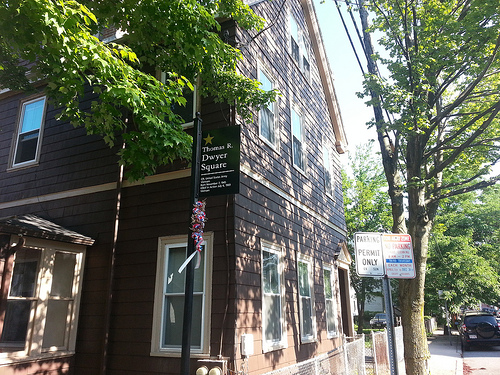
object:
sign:
[198, 123, 243, 196]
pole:
[180, 106, 203, 374]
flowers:
[188, 197, 214, 257]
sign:
[354, 229, 390, 278]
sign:
[381, 227, 417, 283]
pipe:
[93, 4, 136, 375]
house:
[3, 2, 352, 369]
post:
[382, 278, 400, 374]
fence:
[246, 326, 408, 374]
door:
[339, 268, 351, 342]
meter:
[193, 358, 229, 374]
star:
[202, 132, 218, 146]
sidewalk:
[434, 327, 463, 374]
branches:
[456, 6, 498, 72]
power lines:
[336, 1, 391, 66]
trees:
[347, 2, 492, 375]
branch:
[131, 0, 245, 97]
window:
[152, 55, 200, 131]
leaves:
[462, 359, 482, 374]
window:
[9, 88, 55, 173]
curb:
[454, 335, 464, 374]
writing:
[200, 143, 236, 195]